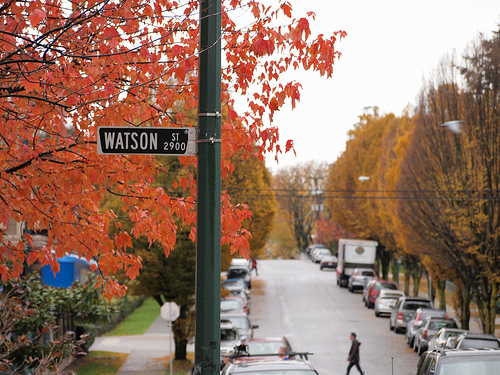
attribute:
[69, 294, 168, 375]
grass — short, green, brown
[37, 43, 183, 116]
leaves — orange, bright, glowing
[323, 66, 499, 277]
trees — brown, orange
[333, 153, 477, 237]
leaves — orange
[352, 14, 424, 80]
clouds — white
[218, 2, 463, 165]
sky — blue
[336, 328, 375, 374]
man — walking, jaywalking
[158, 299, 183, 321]
back — white, octagon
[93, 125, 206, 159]
sign — rectangle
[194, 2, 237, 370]
pole — metal, tall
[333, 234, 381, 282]
box truck — large, parked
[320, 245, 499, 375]
cars — parked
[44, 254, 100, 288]
object — blue